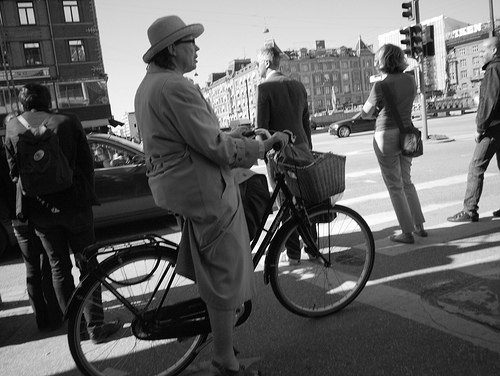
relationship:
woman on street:
[352, 60, 429, 244] [294, 111, 498, 264]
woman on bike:
[114, 8, 245, 357] [74, 205, 353, 364]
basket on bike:
[268, 143, 351, 205] [74, 205, 353, 364]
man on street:
[429, 43, 498, 218] [294, 111, 498, 264]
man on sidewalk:
[11, 91, 110, 329] [167, 243, 457, 359]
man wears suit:
[251, 70, 319, 269] [256, 74, 307, 179]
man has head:
[429, 43, 498, 218] [473, 37, 497, 74]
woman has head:
[352, 60, 429, 244] [367, 42, 413, 88]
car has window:
[0, 136, 146, 243] [88, 134, 138, 162]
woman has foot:
[352, 60, 429, 244] [387, 215, 419, 252]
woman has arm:
[352, 60, 429, 244] [346, 89, 386, 124]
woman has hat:
[114, 8, 245, 357] [134, 17, 196, 59]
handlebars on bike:
[249, 129, 292, 158] [74, 205, 353, 364]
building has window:
[2, 6, 110, 155] [60, 2, 88, 28]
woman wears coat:
[114, 8, 245, 357] [140, 72, 249, 306]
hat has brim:
[134, 17, 196, 59] [151, 31, 196, 63]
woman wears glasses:
[114, 8, 245, 357] [175, 32, 193, 56]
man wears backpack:
[11, 91, 110, 329] [23, 107, 61, 195]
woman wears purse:
[352, 60, 429, 244] [384, 108, 422, 163]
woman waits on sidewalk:
[114, 8, 245, 357] [167, 243, 457, 359]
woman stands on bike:
[114, 8, 245, 357] [74, 205, 353, 364]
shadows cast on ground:
[337, 206, 484, 274] [268, 105, 495, 373]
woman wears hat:
[114, 8, 245, 357] [134, 17, 196, 59]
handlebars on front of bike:
[249, 129, 292, 158] [74, 205, 353, 364]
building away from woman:
[2, 6, 110, 155] [359, 44, 429, 244]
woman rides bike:
[114, 8, 245, 357] [74, 205, 353, 364]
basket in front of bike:
[268, 143, 351, 205] [74, 205, 353, 364]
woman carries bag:
[114, 8, 245, 357] [280, 141, 311, 174]